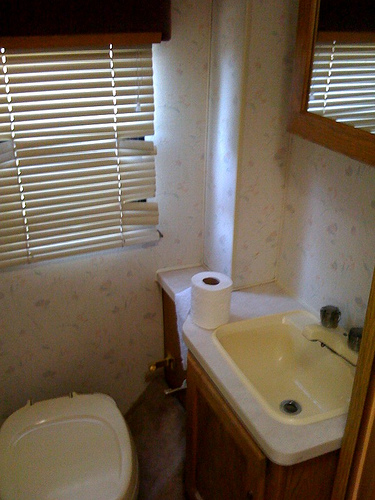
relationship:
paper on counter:
[174, 271, 233, 372] [236, 281, 302, 317]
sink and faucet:
[180, 307, 364, 468] [298, 319, 358, 363]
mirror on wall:
[292, 36, 361, 108] [180, 52, 368, 278]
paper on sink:
[187, 270, 233, 328] [180, 307, 364, 468]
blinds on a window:
[0, 97, 182, 219] [8, 24, 202, 287]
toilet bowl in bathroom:
[0, 390, 140, 499] [0, 0, 373, 498]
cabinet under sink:
[183, 348, 374, 498] [180, 307, 364, 468]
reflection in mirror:
[315, 39, 374, 135] [286, 0, 375, 167]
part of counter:
[252, 288, 275, 302] [154, 260, 366, 467]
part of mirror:
[328, 28, 353, 62] [273, 1, 373, 147]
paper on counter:
[174, 271, 233, 372] [154, 260, 366, 467]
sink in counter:
[194, 317, 364, 445] [154, 260, 366, 467]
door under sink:
[171, 353, 268, 495] [211, 309, 370, 422]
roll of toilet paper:
[189, 271, 234, 334] [186, 267, 234, 331]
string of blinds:
[131, 48, 143, 114] [0, 44, 158, 269]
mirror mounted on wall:
[286, 0, 375, 167] [274, 11, 370, 335]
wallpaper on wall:
[4, 282, 136, 378] [0, 1, 367, 424]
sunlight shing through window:
[55, 62, 198, 226] [2, 44, 162, 275]